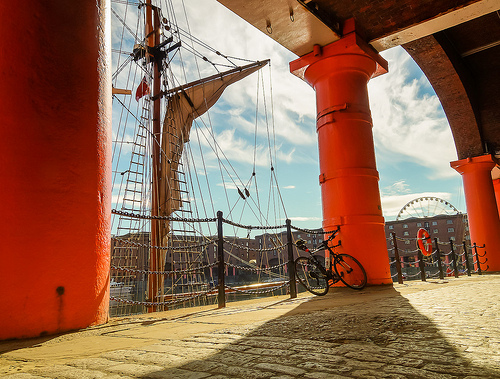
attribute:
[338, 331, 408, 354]
brick — tan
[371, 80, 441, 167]
whitecloud — white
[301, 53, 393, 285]
pillar —  large orange 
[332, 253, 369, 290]
tire — tilted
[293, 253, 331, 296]
tire — tilted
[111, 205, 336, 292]
fence — chain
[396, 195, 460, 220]
ferris wheel — back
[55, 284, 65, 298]
spot — black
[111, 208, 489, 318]
rope fence — rope 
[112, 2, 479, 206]
cloud — white 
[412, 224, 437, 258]
life vest — orange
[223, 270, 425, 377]
bricks — ground 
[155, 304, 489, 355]
surface — cobblestone